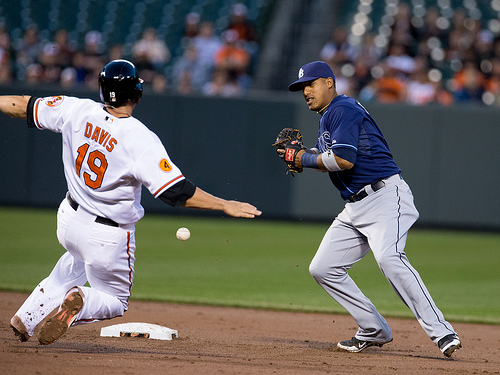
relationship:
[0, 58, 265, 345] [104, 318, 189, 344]
baseball players sliding to base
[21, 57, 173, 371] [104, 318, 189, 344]
team member running for base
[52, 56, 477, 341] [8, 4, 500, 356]
baseball players during game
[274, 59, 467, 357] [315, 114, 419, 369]
person in uniform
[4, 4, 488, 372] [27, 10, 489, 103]
stadium full of spectators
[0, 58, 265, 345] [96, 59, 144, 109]
baseball players wearing helmet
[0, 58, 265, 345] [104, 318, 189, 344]
baseball players sliding into base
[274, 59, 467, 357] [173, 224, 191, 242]
person going for ball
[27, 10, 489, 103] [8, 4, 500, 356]
spectators at game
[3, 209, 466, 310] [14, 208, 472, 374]
grass of baseball field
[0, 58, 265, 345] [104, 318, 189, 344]
baseball players going to base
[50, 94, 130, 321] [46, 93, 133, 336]
jersey of baseball player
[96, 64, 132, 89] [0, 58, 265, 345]
helmet of baseball players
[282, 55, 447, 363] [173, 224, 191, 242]
person playing ball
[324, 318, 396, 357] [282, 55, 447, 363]
foot of person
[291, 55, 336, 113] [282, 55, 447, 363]
head of person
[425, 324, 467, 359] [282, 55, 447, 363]
foot of person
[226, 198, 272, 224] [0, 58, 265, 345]
hand of baseball players